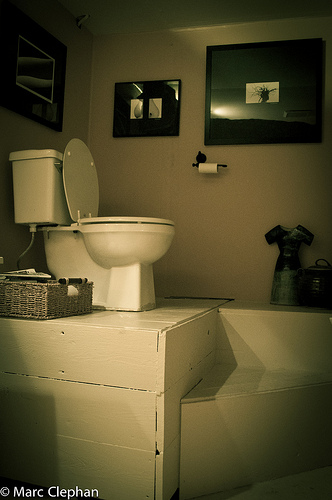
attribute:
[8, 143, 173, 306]
toilet — white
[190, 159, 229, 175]
towel — white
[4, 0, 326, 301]
wall — white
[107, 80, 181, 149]
frame — black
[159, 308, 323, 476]
stairs — white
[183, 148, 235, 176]
holder — black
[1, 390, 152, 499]
drawer — white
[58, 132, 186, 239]
seat — open